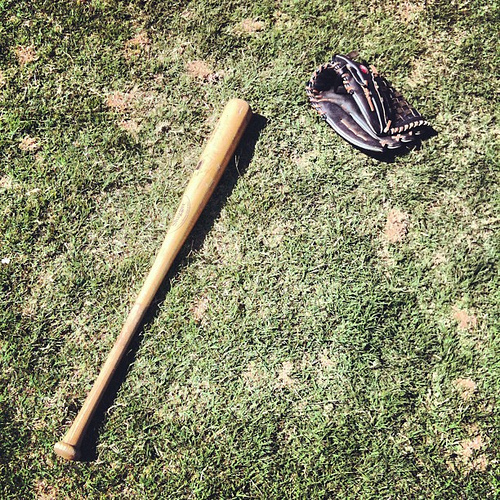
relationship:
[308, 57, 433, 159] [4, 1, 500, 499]
baseball glove on ground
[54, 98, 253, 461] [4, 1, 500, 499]
baseball bat on ground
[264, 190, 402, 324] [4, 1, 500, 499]
grass on ground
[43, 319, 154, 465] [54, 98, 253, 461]
handle on baseball bat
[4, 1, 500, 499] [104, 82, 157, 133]
ground has patches of brown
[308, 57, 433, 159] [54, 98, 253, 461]
baseball glove and a baseball bat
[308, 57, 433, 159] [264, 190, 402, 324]
baseball glove on grass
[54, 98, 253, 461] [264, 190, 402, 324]
baseball bat on grass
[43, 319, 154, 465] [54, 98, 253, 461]
handle of baseball bat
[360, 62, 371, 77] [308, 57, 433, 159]
label on baseball glove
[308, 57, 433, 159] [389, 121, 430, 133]
baseball glove has stitching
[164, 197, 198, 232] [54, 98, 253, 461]
label on baseball bat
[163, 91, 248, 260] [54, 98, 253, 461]
barrel of baseball bat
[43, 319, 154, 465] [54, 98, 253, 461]
handle on bottom of baseball bat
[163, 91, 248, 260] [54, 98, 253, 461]
barrel at top of baseball bat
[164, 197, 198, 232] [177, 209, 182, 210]
label on bat black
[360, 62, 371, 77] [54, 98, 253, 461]
label on baseball bat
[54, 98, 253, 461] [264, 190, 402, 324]
baseball bat laying on grass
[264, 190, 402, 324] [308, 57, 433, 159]
grass between bat and baseball glove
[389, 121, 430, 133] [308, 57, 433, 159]
stitching on baseball glove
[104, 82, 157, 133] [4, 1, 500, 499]
brown patches on ground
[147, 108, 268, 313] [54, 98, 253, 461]
shadow from baseball bat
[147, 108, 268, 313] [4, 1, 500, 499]
shadow on ground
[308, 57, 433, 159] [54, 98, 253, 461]
baseball glove along with baseball bat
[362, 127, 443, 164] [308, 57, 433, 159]
shadow from baseball glove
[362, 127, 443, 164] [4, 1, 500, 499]
shadow on ground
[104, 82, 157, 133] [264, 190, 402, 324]
brown in grass